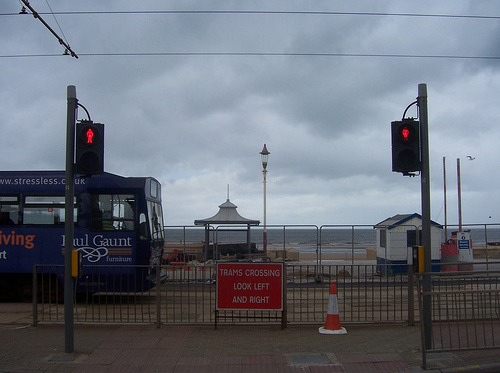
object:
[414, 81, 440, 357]
pole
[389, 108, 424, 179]
traffic light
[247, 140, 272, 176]
light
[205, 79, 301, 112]
sky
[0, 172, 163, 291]
tram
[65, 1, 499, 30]
cables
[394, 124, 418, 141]
sign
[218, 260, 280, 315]
sign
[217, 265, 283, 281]
text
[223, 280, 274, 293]
look left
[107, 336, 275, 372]
sidewalk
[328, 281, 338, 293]
cone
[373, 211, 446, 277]
building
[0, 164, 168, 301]
bus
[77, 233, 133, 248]
print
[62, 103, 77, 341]
post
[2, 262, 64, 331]
gate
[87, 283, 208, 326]
road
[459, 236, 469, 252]
warning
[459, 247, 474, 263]
board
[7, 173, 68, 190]
advertisement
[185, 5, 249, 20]
wires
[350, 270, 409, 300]
fence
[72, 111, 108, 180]
signals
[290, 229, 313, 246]
water